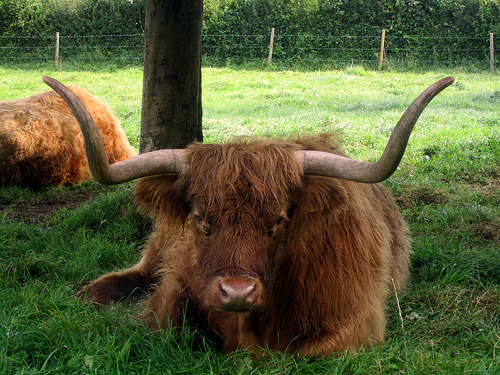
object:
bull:
[0, 83, 140, 188]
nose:
[215, 275, 263, 306]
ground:
[369, 99, 392, 129]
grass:
[456, 150, 494, 199]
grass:
[128, 340, 184, 374]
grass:
[0, 310, 75, 375]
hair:
[184, 140, 292, 213]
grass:
[256, 75, 368, 122]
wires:
[417, 31, 465, 70]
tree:
[137, 0, 205, 153]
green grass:
[74, 205, 112, 244]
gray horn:
[287, 75, 458, 184]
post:
[377, 29, 386, 71]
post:
[267, 27, 276, 66]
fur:
[300, 275, 381, 319]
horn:
[40, 74, 192, 187]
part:
[225, 207, 247, 228]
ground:
[451, 89, 500, 127]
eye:
[190, 211, 208, 228]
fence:
[0, 27, 500, 74]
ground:
[1, 65, 28, 95]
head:
[40, 74, 455, 315]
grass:
[433, 316, 500, 375]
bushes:
[442, 0, 499, 29]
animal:
[38, 73, 456, 360]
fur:
[319, 223, 387, 294]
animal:
[36, 63, 455, 354]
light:
[226, 85, 334, 138]